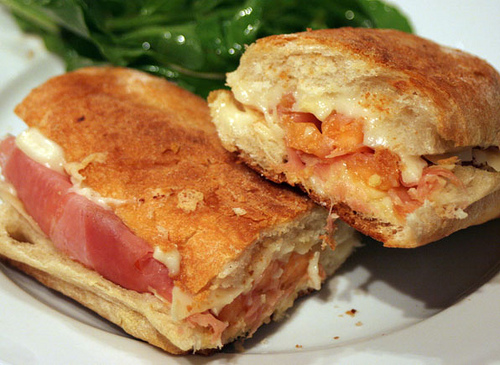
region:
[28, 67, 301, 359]
sandwich on a white plate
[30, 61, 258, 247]
the top of a sandwich roll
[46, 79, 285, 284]
golden brown sandwich roll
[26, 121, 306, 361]
meat inside a sandwich roll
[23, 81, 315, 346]
melted cheese inside a sandwich roll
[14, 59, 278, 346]
meat and cheese inside a sandwich roll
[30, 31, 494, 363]
two pieces of sandwich on a white plate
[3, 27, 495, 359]
two parts of sandwich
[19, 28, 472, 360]
two parts of a sandwich on a plate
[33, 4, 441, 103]
greens next to a sandwich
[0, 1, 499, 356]
a sandwich on a white plate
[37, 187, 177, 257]
pink ham on a sandwich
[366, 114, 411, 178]
white cheese on a sandwich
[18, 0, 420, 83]
a green leafy vegetable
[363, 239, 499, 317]
a shadow on a plate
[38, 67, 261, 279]
the brown crust on the bread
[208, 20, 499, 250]
a half of a sandwich on the right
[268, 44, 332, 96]
white dough of the bread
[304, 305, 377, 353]
bread crumbs on a plate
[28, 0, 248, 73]
a shiny green vegetable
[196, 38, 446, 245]
The side of a toasted sandwich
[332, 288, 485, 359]
A white plate with some crumbs on it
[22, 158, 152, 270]
A slice of luncheon meat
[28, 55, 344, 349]
Half of a toasted sandwich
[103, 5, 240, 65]
Moist green leaves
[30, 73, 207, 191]
Flaky brown bread with cheese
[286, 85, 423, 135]
Glistening melted cheese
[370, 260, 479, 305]
A dark shadow with light border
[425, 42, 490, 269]
This side of a cheese and meat sandwich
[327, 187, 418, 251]
Crispy edge of bread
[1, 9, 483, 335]
food on the plate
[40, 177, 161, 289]
meat in the bread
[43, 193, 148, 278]
red meat in the photo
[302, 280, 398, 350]
crumbs on the plate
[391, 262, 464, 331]
shadow on the plate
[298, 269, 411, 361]
white plate in photo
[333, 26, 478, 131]
top part of the bun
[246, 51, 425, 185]
cheese in the bun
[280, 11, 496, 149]
brown and white sandwich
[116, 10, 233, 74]
green food in the photo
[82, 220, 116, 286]
This is fatty ham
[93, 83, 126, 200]
There are crispy buns here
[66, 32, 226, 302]
This photo is quite detailed